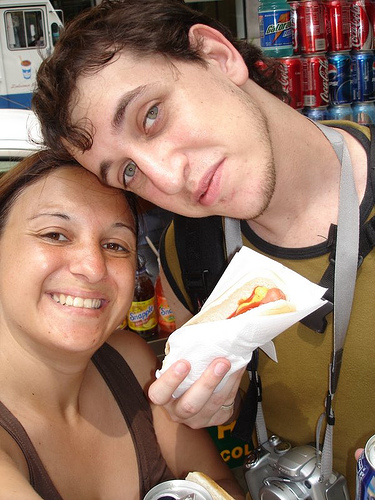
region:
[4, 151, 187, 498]
A woman in a brown shirt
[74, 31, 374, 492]
a man in a yellow shirt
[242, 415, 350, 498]
a silver colored camera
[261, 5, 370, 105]
some cans of coca cola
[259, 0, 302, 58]
a bottle of gatorade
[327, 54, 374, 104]
two cans of pepsi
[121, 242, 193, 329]
some bottles of snapple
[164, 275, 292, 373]
A hot dog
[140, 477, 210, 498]
an aluminum drinking can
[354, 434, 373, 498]
an aluminum drinking can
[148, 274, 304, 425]
person holding a hotdog.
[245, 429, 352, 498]
the camera is silver.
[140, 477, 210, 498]
the can is open.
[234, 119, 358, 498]
camera around man's neck.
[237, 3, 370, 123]
beverages in the background.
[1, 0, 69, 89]
the truck is white.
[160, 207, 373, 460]
man's shirt is green.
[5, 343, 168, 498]
woman's shirt is brown.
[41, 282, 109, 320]
the woman is smiling.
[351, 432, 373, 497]
man holding a can.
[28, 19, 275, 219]
a man's leaning face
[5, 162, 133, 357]
a woman's smiling face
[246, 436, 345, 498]
a silver digital camera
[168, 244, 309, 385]
a wrapped hot dog bun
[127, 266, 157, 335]
a glass bottle of Snapple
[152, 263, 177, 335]
an orange bottle of Snapple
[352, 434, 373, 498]
a blue aluminum can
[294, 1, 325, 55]
a red can of soda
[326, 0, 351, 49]
a red can of soda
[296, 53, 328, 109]
a red can of soda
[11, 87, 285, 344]
smiling couple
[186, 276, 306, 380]
hot dog with ketchup and mustard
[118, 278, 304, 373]
snapple bottles and hot dog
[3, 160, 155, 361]
girl with brown hair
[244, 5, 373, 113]
assortment of drinks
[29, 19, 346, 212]
young man with facial hair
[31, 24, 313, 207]
young man with brown hair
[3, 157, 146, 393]
young girl with brown eyes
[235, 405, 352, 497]
silver camera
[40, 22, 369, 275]
young man with tank top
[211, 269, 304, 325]
a frank on a bun with mustard and ketchup on a napkin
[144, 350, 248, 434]
hand holding on to a frank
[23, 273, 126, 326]
a woman with a big smile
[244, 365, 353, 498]
a gray camera hanging from a strap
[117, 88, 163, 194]
a pair of blue gray eyes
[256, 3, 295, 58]
a gatorade bottle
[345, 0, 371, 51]
A diet coke can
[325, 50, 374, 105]
Two pepsi cans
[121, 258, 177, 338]
Two snapple bottles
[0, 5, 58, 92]
Side window of an ice cream truck